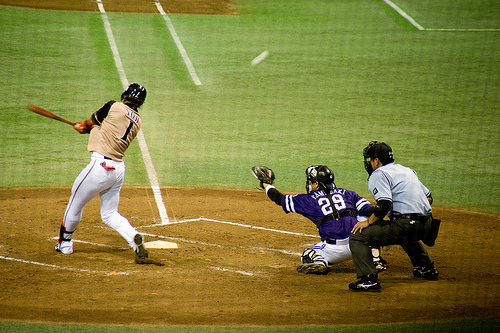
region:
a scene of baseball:
[3, 5, 498, 317]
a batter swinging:
[16, 72, 171, 274]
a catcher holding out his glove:
[229, 152, 396, 282]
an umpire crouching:
[321, 125, 451, 299]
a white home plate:
[126, 232, 203, 267]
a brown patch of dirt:
[5, 172, 472, 332]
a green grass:
[3, 5, 493, 206]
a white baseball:
[235, 36, 279, 79]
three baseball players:
[16, 59, 478, 299]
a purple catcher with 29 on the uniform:
[250, 158, 396, 288]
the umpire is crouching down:
[345, 138, 453, 293]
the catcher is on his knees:
[233, 147, 388, 289]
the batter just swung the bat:
[15, 65, 165, 275]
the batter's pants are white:
[51, 150, 141, 271]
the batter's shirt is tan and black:
[77, 100, 147, 155]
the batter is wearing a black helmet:
[113, 80, 152, 108]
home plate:
[130, 226, 186, 257]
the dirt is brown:
[4, 185, 489, 330]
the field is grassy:
[14, 7, 482, 201]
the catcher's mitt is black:
[242, 162, 275, 191]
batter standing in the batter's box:
[18, 54, 180, 272]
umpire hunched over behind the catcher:
[249, 131, 452, 305]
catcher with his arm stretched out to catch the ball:
[236, 144, 387, 276]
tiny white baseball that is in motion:
[247, 41, 274, 71]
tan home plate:
[138, 233, 188, 256]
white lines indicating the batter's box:
[2, 225, 162, 290]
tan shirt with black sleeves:
[51, 88, 159, 159]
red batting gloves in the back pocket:
[95, 158, 113, 178]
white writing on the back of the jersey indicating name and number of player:
[310, 189, 356, 230]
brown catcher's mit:
[247, 158, 277, 188]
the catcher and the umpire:
[221, 110, 475, 305]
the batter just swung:
[18, 74, 205, 285]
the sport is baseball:
[26, 45, 478, 297]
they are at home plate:
[16, 47, 499, 303]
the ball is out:
[234, 35, 340, 112]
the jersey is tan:
[20, 57, 206, 294]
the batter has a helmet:
[12, 52, 237, 327]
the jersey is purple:
[223, 110, 406, 302]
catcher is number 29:
[286, 152, 381, 272]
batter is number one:
[0, 40, 212, 278]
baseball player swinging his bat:
[11, 65, 164, 267]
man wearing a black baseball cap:
[117, 73, 155, 108]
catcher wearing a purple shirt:
[250, 146, 369, 267]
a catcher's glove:
[248, 157, 287, 199]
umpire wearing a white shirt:
[350, 142, 449, 212]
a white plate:
[146, 225, 181, 259]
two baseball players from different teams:
[21, 36, 363, 301]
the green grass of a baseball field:
[321, 39, 456, 122]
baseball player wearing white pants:
[73, 150, 147, 253]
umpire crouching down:
[351, 137, 446, 299]